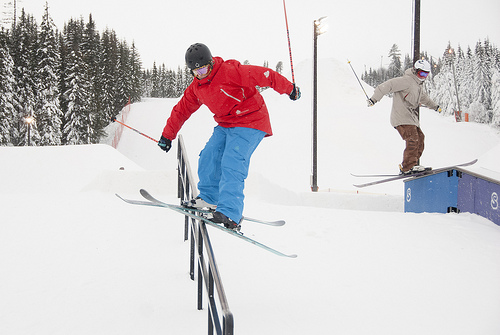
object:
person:
[156, 42, 302, 229]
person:
[368, 57, 443, 177]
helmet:
[184, 43, 213, 69]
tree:
[33, 0, 61, 145]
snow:
[0, 80, 498, 334]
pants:
[197, 124, 267, 225]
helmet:
[413, 58, 431, 74]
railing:
[177, 133, 234, 335]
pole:
[283, 1, 296, 88]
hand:
[290, 84, 302, 101]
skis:
[114, 192, 285, 226]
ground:
[0, 86, 499, 335]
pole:
[312, 19, 318, 190]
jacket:
[161, 57, 295, 140]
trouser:
[395, 124, 425, 173]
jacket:
[369, 68, 438, 127]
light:
[313, 16, 330, 37]